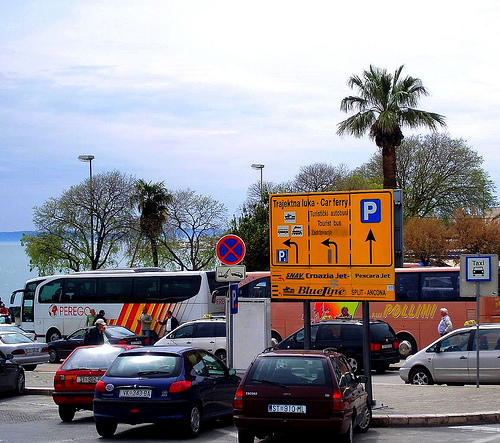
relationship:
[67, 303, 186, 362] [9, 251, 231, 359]
people outside bus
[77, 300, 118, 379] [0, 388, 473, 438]
man near road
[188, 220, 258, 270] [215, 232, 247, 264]
sign has an sign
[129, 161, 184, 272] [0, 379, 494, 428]
tree near road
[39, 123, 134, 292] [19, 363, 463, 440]
light pole near road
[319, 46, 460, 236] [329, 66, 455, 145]
tree has leaves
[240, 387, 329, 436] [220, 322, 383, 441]
license plate on rear of car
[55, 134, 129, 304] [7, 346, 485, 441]
street lamp near road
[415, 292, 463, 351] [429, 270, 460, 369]
man has a belly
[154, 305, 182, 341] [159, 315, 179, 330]
man in jacket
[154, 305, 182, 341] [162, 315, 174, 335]
man in shirt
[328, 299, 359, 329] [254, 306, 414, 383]
man leaning on mini van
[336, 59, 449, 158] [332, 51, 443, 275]
fronds on palm tree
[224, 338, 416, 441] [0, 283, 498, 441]
car in parking lot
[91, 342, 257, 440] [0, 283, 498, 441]
car in parking lot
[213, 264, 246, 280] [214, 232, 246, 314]
tow sign on traffic sign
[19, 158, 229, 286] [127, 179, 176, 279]
trees next to palm tree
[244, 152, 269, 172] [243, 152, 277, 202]
light on pole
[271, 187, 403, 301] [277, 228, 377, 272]
sign with arrows